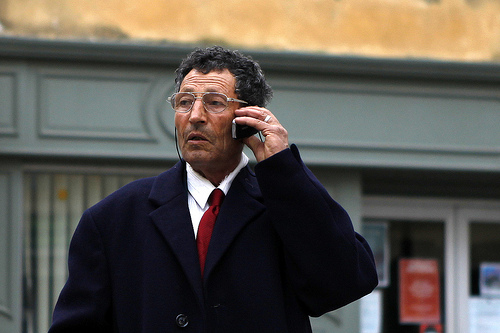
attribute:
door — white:
[346, 193, 473, 331]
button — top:
[175, 313, 187, 328]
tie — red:
[194, 187, 224, 276]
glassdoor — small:
[447, 220, 492, 262]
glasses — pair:
[167, 90, 247, 115]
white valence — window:
[31, 177, 56, 331]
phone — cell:
[232, 107, 279, 145]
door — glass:
[363, 215, 458, 331]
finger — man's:
[234, 108, 277, 127]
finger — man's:
[226, 112, 280, 137]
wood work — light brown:
[0, 0, 497, 63]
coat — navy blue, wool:
[3, 123, 385, 323]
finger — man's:
[235, 107, 281, 131]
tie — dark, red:
[196, 185, 226, 275]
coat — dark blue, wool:
[46, 142, 377, 332]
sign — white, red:
[394, 254, 446, 329]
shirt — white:
[181, 150, 253, 241]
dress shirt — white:
[181, 144, 248, 267]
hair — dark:
[171, 49, 267, 111]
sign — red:
[394, 249, 451, 329]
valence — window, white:
[20, 173, 186, 331]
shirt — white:
[165, 145, 276, 275]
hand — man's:
[222, 98, 305, 166]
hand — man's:
[225, 105, 305, 163]